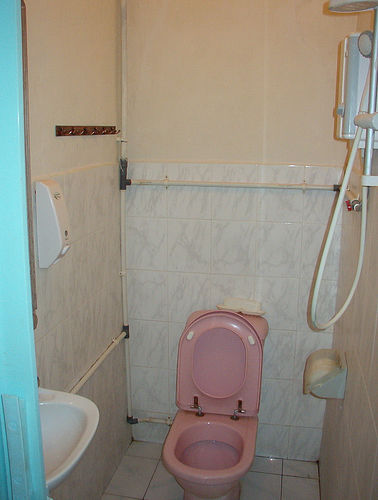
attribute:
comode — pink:
[162, 311, 271, 499]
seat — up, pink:
[176, 309, 262, 419]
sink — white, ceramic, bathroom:
[38, 385, 104, 493]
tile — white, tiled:
[100, 438, 324, 500]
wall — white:
[120, 0, 356, 168]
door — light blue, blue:
[2, 0, 47, 500]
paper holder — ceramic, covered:
[301, 349, 346, 401]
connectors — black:
[120, 162, 138, 426]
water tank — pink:
[181, 311, 271, 347]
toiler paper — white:
[300, 348, 340, 395]